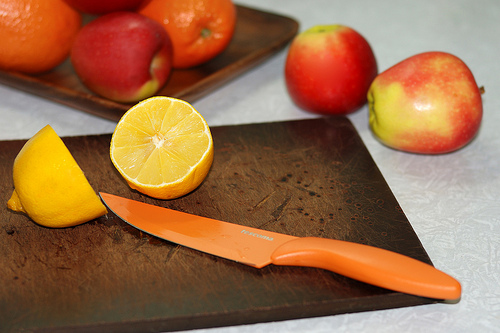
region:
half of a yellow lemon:
[7, 126, 97, 233]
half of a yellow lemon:
[117, 96, 203, 195]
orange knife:
[133, 196, 444, 308]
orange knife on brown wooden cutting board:
[110, 203, 450, 308]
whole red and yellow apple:
[382, 43, 473, 155]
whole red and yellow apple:
[296, 1, 367, 121]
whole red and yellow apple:
[77, 1, 155, 88]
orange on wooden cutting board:
[172, 1, 232, 50]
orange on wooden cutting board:
[7, 6, 71, 63]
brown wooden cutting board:
[31, 248, 194, 322]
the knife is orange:
[190, 216, 432, 283]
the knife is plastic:
[183, 228, 388, 284]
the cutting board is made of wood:
[270, 145, 378, 200]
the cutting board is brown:
[290, 146, 365, 206]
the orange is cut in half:
[113, 111, 261, 194]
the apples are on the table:
[284, 56, 479, 126]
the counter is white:
[435, 178, 492, 259]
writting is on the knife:
[229, 218, 280, 245]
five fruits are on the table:
[29, 10, 469, 105]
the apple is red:
[91, 34, 171, 86]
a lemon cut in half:
[11, 75, 255, 260]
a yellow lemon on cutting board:
[19, 81, 206, 260]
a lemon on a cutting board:
[15, 97, 260, 273]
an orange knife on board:
[72, 150, 454, 319]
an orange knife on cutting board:
[79, 150, 469, 317]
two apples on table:
[248, 3, 498, 198]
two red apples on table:
[264, 10, 496, 163]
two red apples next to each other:
[294, 11, 495, 187]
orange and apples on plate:
[8, 7, 253, 96]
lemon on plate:
[1, 65, 454, 331]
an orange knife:
[124, 207, 471, 314]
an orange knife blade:
[134, 205, 264, 274]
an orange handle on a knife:
[283, 232, 458, 304]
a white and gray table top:
[449, 233, 496, 285]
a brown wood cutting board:
[14, 237, 167, 312]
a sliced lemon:
[4, 115, 219, 215]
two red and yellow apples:
[288, 16, 482, 165]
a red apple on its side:
[70, 17, 171, 89]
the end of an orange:
[160, 0, 235, 56]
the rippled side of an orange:
[2, 2, 73, 60]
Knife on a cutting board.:
[94, 186, 463, 298]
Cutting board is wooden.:
[33, 262, 215, 319]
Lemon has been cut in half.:
[8, 95, 219, 220]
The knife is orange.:
[90, 187, 447, 299]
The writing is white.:
[233, 220, 281, 251]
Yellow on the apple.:
[368, 74, 415, 145]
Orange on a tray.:
[151, 0, 252, 64]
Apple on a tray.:
[70, 13, 170, 95]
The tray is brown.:
[19, 0, 302, 135]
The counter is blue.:
[424, 162, 495, 251]